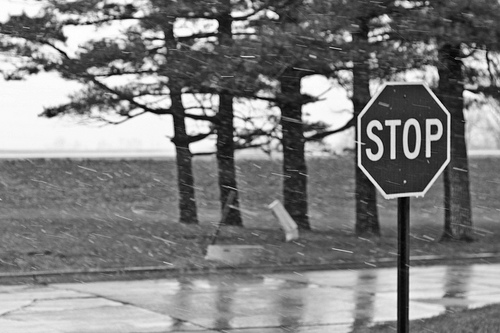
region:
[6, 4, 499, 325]
the photo is black and white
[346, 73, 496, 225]
the stop sign on the pole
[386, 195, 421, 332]
the pole is metal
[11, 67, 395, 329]
the snow is falling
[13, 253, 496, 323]
the ground is wet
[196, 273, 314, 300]
puddle on the ground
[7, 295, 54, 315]
cracks on the ground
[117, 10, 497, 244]
trees behind the stop sign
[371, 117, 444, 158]
letters on the stop sign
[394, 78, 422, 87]
edge of the stop sign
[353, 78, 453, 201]
Typical stop sign on a street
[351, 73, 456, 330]
Black and white stop sign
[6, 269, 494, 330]
Road in the background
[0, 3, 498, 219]
Group of trees in the background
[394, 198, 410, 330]
Pole holding up the stop sign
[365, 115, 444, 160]
Sign that reads "stop"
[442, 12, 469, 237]
Large base of a tree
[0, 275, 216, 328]
Cracked part of the street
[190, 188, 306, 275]
Broken parts of something on side of the road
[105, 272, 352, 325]
Group of puddles on street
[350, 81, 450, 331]
stop sign on a pole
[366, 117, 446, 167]
white writing in all caps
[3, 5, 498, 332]
rain flying through the air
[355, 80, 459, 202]
white border around the sign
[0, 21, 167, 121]
branches sticking out from the tree trunk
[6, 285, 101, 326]
crack in the pavement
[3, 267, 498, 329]
a paved road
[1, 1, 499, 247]
a row of trees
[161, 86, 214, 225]
skinny tree trunk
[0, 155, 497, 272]
grass on the ground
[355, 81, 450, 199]
stop sign in black and white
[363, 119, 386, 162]
the letter s on a sign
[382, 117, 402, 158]
the letter t on a sign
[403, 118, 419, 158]
the letter o on a stop sign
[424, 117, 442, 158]
the letter p on a stop sign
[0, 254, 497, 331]
road that is wet because of rain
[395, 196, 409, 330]
pole holding up a stop sign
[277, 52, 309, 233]
trunk of a tree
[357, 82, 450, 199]
hexagon of a stop sign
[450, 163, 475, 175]
rain photographed while windy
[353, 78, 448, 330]
stop sign stands against the elements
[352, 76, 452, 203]
sign is shaped like an octagon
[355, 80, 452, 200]
sign has a white perimeter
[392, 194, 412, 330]
pole holds up sign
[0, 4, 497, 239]
trees are in the background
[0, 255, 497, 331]
street is wet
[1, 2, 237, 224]
tree is in background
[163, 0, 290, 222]
tree is in background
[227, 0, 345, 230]
tree is in background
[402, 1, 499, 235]
tree is in background